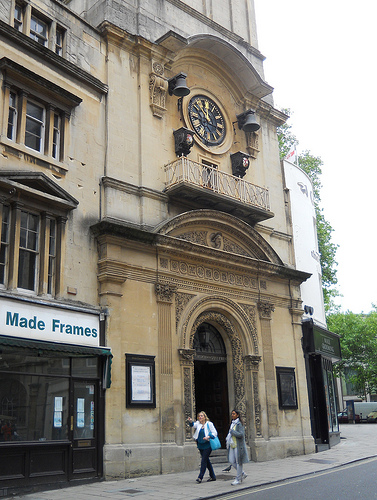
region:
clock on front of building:
[182, 85, 236, 155]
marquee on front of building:
[123, 350, 159, 408]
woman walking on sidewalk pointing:
[184, 410, 222, 482]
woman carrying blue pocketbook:
[186, 410, 222, 483]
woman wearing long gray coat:
[224, 407, 250, 485]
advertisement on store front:
[4, 306, 102, 342]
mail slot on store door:
[76, 438, 92, 447]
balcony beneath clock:
[162, 156, 274, 226]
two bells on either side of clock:
[163, 69, 260, 132]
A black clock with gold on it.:
[187, 94, 228, 146]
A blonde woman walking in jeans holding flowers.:
[184, 410, 217, 481]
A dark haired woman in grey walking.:
[225, 408, 249, 486]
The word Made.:
[6, 310, 44, 329]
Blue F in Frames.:
[51, 318, 60, 332]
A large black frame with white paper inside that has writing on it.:
[124, 352, 157, 407]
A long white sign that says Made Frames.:
[0, 295, 101, 348]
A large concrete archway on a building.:
[177, 290, 258, 468]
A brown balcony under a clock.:
[162, 158, 274, 223]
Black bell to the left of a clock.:
[171, 77, 190, 97]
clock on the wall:
[189, 94, 225, 144]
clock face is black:
[189, 93, 225, 144]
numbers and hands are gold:
[189, 95, 224, 141]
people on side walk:
[185, 407, 250, 485]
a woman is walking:
[185, 410, 220, 481]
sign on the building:
[124, 352, 156, 408]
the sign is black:
[276, 363, 298, 408]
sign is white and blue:
[0, 295, 98, 345]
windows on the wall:
[1, 197, 59, 296]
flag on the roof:
[285, 140, 299, 164]